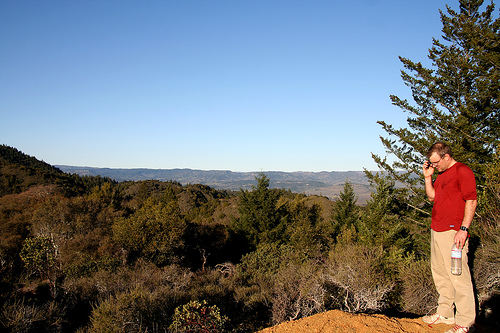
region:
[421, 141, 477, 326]
a man on top of a mountain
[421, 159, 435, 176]
man holding a cell phone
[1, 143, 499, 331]
threes on the hill below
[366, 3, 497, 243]
a big pine tree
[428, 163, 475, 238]
man wearing a red T-shirt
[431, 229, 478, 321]
man wearing tan pants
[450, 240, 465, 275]
man holding a bottle of water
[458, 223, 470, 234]
man wearing a black watch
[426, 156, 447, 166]
man wearing glasses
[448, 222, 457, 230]
a logo on man's shirt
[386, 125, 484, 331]
the man is talking on phone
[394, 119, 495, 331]
he is holding a bottle on his hands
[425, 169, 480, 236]
the shirt is red in colour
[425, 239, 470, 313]
the pant is brown in colour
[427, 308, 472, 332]
the shoes are red in colour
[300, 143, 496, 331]
he is standing on a brown soil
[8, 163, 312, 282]
the trees are brown in colour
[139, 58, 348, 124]
the sky is blue in colour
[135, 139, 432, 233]
the landscape is mountainous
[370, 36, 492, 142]
the branches are pointed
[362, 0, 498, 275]
tall tree on nature area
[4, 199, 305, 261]
trees in the overlooked area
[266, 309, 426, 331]
mound of dirt on ground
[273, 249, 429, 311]
bushes near the ground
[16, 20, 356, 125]
blue sky with no clouds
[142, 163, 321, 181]
the area to the distance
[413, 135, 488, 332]
person standing on dirt mound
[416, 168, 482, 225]
shirt on the person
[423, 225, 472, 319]
pants on the person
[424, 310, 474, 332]
shoes on the person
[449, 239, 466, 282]
a man holding a water bottle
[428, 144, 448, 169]
a man wearing glasses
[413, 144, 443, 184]
a man holding a cell phone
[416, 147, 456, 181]
a man using a cell phone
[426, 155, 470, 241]
a ma wearing a red shirt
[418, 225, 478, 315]
a man wearing tan pants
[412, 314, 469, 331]
a man wearing tennis shoes with red laces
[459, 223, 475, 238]
a man wearing a black watch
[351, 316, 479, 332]
a man standing on a mound of dirt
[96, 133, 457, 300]
a man standing on a cliff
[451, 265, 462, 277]
part of a bottle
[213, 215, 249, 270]
part fo a shade